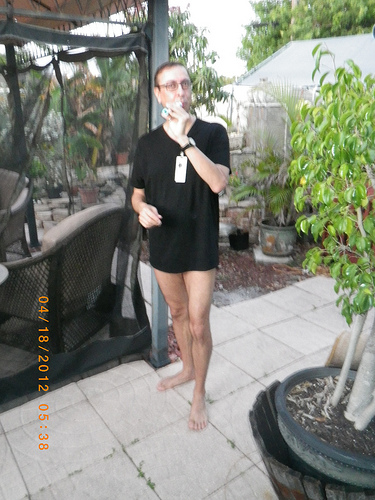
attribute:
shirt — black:
[136, 117, 237, 234]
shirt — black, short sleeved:
[131, 120, 232, 270]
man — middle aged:
[129, 62, 233, 430]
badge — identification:
[160, 146, 205, 185]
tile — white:
[8, 401, 168, 497]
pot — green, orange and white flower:
[238, 206, 298, 266]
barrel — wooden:
[269, 353, 370, 473]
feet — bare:
[151, 362, 214, 434]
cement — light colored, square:
[5, 270, 370, 494]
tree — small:
[285, 41, 373, 431]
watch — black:
[176, 134, 199, 152]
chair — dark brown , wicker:
[34, 194, 124, 323]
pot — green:
[274, 367, 374, 487]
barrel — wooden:
[245, 330, 373, 499]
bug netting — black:
[0, 7, 153, 408]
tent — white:
[201, 26, 367, 216]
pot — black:
[228, 230, 249, 250]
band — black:
[181, 125, 191, 177]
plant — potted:
[281, 72, 374, 434]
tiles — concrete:
[0, 268, 367, 498]